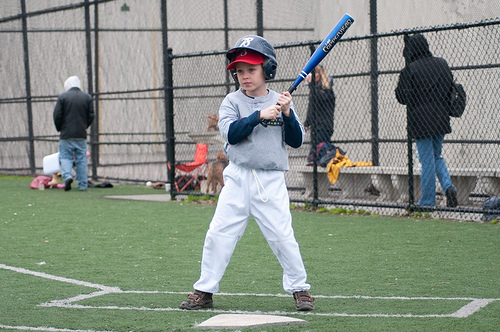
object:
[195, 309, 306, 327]
home base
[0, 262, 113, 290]
line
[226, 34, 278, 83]
helmet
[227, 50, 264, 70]
baseball hat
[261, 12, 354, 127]
baseball bat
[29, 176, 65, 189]
child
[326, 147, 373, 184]
jacket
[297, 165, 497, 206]
bench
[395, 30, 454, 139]
jacket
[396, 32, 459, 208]
person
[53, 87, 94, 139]
jacket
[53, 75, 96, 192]
man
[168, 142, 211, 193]
seat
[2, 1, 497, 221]
fence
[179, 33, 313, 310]
kid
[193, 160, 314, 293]
pants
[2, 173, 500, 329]
grass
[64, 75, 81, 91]
hood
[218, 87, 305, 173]
shirt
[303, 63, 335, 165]
woman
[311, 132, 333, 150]
jeans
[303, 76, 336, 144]
coat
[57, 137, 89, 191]
jeans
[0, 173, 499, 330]
field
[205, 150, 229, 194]
dog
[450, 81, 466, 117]
backpack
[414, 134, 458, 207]
jeans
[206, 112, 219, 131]
dog